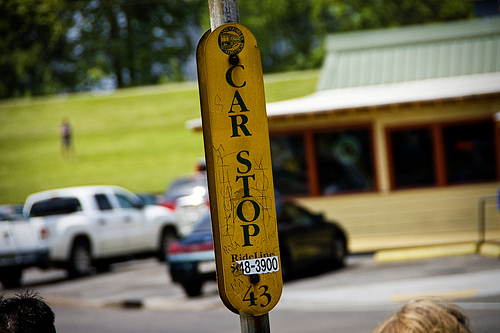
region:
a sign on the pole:
[186, 18, 289, 319]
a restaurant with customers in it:
[266, 27, 499, 248]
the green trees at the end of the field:
[1, 5, 327, 90]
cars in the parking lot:
[4, 186, 344, 295]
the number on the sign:
[231, 279, 273, 313]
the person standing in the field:
[52, 115, 79, 160]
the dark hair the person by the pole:
[6, 292, 54, 331]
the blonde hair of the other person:
[368, 296, 458, 330]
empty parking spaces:
[352, 240, 491, 306]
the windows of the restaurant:
[281, 117, 495, 195]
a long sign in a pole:
[190, 16, 289, 320]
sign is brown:
[190, 12, 290, 332]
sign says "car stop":
[189, 14, 297, 325]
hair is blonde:
[367, 283, 479, 331]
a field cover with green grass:
[1, 82, 200, 192]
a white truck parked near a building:
[3, 175, 180, 282]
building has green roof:
[178, 16, 498, 253]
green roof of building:
[309, 18, 499, 84]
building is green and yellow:
[176, 18, 498, 258]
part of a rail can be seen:
[463, 188, 498, 253]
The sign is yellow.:
[181, 37, 285, 299]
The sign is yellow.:
[142, 8, 270, 252]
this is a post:
[220, 86, 265, 169]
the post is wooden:
[215, 108, 263, 168]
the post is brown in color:
[207, 127, 263, 167]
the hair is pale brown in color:
[400, 302, 451, 332]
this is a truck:
[10, 180, 137, 272]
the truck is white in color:
[107, 210, 150, 238]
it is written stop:
[227, 145, 263, 250]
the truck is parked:
[16, 186, 140, 261]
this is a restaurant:
[355, 91, 467, 247]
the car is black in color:
[296, 219, 338, 265]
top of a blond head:
[364, 294, 468, 331]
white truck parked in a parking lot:
[2, 178, 177, 288]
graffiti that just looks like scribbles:
[214, 141, 239, 251]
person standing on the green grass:
[51, 116, 90, 163]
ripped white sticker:
[233, 256, 280, 278]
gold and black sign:
[185, 23, 297, 326]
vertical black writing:
[220, 62, 268, 256]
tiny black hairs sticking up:
[16, 288, 42, 298]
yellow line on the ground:
[375, 286, 480, 304]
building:
[166, 18, 499, 242]